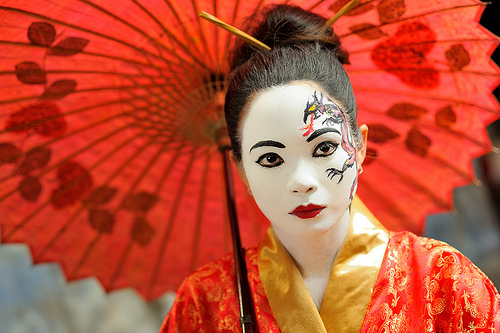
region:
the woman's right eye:
[250, 147, 288, 173]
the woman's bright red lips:
[280, 199, 338, 224]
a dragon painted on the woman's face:
[300, 88, 362, 190]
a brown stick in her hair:
[187, 6, 272, 55]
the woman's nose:
[287, 173, 320, 194]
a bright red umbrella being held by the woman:
[3, 3, 490, 305]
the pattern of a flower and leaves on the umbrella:
[13, 15, 85, 142]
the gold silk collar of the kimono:
[251, 216, 378, 326]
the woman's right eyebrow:
[248, 132, 288, 149]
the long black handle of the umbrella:
[210, 136, 275, 330]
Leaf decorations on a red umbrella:
[0, 16, 157, 247]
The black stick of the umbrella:
[216, 143, 256, 331]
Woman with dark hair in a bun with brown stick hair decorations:
[188, 0, 368, 54]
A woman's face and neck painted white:
[226, 78, 378, 296]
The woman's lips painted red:
[286, 201, 340, 222]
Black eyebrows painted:
[243, 125, 344, 150]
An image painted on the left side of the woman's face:
[297, 93, 361, 183]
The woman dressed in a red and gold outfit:
[146, 200, 497, 331]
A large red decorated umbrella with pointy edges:
[0, 0, 499, 301]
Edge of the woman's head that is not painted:
[236, 92, 253, 137]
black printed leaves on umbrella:
[22, 29, 161, 254]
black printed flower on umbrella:
[17, 96, 94, 149]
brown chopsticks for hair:
[175, 6, 385, 63]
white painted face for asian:
[243, 55, 408, 262]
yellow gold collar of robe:
[244, 255, 374, 329]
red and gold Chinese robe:
[196, 240, 476, 325]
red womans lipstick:
[282, 205, 334, 222]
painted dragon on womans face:
[300, 89, 402, 208]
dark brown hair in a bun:
[225, 13, 366, 102]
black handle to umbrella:
[201, 134, 264, 331]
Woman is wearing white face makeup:
[203, 47, 431, 291]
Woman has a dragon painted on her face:
[293, 87, 395, 209]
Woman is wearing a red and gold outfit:
[160, 217, 495, 331]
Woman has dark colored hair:
[187, 17, 384, 154]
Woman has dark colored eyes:
[246, 123, 363, 190]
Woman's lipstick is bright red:
[273, 198, 343, 245]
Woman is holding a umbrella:
[5, 5, 495, 316]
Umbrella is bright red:
[0, 2, 495, 319]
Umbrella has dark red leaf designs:
[7, 93, 180, 283]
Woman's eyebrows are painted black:
[227, 111, 353, 160]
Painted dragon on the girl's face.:
[300, 94, 357, 185]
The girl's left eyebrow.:
[244, 141, 289, 151]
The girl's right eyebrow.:
[304, 129, 345, 142]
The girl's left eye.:
[252, 155, 284, 169]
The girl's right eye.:
[306, 142, 341, 156]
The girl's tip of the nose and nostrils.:
[282, 174, 321, 196]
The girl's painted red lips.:
[285, 204, 325, 218]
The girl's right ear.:
[352, 120, 367, 177]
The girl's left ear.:
[228, 153, 247, 186]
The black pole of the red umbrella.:
[222, 147, 251, 332]